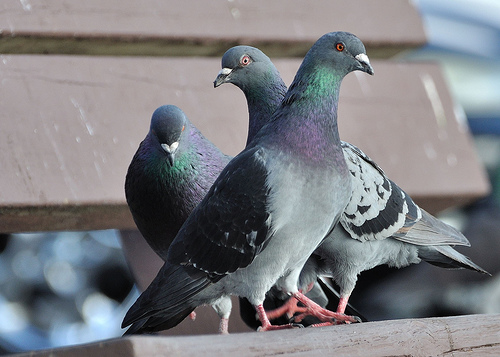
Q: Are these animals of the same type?
A: Yes, all the animals are pigeons.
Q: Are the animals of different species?
A: No, all the animals are pigeons.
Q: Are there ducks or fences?
A: No, there are no fences or ducks.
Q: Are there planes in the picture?
A: No, there are no planes.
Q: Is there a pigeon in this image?
A: Yes, there is a pigeon.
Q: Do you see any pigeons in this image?
A: Yes, there is a pigeon.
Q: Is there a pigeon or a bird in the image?
A: Yes, there is a pigeon.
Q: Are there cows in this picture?
A: No, there are no cows.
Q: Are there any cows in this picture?
A: No, there are no cows.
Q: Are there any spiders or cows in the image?
A: No, there are no cows or spiders.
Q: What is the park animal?
A: The animal is a pigeon.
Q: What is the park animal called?
A: The animal is a pigeon.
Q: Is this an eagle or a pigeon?
A: This is a pigeon.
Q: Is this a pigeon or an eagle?
A: This is a pigeon.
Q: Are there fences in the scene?
A: No, there are no fences.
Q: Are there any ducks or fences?
A: No, there are no fences or ducks.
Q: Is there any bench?
A: Yes, there is a bench.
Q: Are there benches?
A: Yes, there is a bench.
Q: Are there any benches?
A: Yes, there is a bench.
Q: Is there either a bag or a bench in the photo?
A: Yes, there is a bench.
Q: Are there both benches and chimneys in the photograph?
A: No, there is a bench but no chimneys.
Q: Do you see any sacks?
A: No, there are no sacks.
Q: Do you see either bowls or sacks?
A: No, there are no sacks or bowls.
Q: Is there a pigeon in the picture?
A: Yes, there is a pigeon.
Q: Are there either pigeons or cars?
A: Yes, there is a pigeon.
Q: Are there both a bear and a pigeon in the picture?
A: No, there is a pigeon but no bears.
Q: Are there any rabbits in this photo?
A: No, there are no rabbits.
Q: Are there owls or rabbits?
A: No, there are no rabbits or owls.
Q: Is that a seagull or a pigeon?
A: That is a pigeon.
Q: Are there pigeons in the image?
A: Yes, there is a pigeon.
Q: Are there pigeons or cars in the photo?
A: Yes, there is a pigeon.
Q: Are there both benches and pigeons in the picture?
A: Yes, there are both a pigeon and a bench.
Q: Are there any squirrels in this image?
A: No, there are no squirrels.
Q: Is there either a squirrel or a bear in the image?
A: No, there are no squirrels or bears.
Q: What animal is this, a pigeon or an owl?
A: This is a pigeon.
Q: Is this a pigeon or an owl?
A: This is a pigeon.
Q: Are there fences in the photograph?
A: No, there are no fences.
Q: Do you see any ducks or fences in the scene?
A: No, there are no fences or ducks.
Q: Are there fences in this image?
A: No, there are no fences.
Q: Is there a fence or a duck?
A: No, there are no fences or ducks.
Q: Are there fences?
A: No, there are no fences.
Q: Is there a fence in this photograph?
A: No, there are no fences.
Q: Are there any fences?
A: No, there are no fences.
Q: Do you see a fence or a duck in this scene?
A: No, there are no fences or ducks.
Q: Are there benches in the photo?
A: Yes, there is a bench.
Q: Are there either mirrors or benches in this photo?
A: Yes, there is a bench.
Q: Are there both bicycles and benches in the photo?
A: No, there is a bench but no bicycles.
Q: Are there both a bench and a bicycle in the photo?
A: No, there is a bench but no bicycles.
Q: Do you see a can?
A: No, there are no cans.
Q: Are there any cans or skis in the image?
A: No, there are no cans or skis.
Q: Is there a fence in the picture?
A: No, there are no fences.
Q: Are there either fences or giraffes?
A: No, there are no fences or giraffes.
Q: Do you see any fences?
A: No, there are no fences.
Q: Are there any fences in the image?
A: No, there are no fences.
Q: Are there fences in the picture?
A: No, there are no fences.